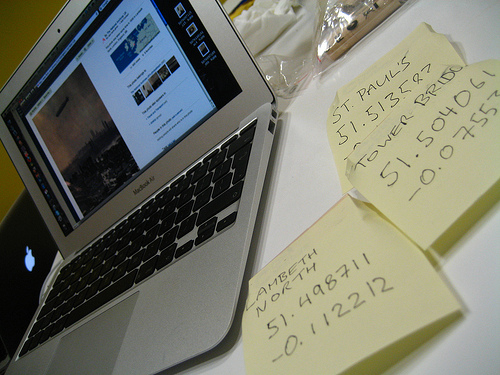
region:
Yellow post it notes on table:
[262, 12, 495, 373]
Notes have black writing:
[261, 19, 483, 354]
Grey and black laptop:
[11, 3, 271, 370]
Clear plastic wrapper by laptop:
[253, 7, 377, 110]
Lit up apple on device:
[8, 224, 45, 285]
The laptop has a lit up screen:
[8, 3, 258, 195]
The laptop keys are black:
[28, 121, 257, 338]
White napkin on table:
[237, 5, 319, 47]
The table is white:
[183, 8, 491, 351]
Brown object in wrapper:
[312, 6, 401, 61]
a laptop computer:
[2, 5, 394, 330]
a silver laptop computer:
[3, 12, 355, 374]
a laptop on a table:
[4, 8, 371, 372]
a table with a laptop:
[4, 6, 363, 362]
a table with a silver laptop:
[7, 16, 405, 373]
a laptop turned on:
[4, 6, 336, 368]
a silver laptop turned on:
[4, 5, 371, 355]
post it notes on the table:
[205, 23, 490, 366]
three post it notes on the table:
[221, 28, 496, 305]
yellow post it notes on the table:
[219, 53, 498, 358]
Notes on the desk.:
[303, 42, 496, 235]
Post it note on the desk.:
[245, 247, 462, 372]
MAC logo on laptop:
[7, 215, 64, 284]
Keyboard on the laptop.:
[30, 229, 302, 345]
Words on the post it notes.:
[318, 84, 483, 186]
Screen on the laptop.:
[8, 30, 288, 187]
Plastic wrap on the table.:
[258, 13, 397, 74]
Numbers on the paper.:
[256, 249, 443, 361]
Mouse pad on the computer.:
[52, 313, 161, 372]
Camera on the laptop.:
[28, 12, 77, 44]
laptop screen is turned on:
[0, 1, 249, 183]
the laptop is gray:
[3, 1, 243, 355]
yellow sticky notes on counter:
[229, 48, 479, 356]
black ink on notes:
[240, 62, 497, 350]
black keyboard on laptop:
[28, 201, 303, 311]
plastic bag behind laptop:
[228, 1, 410, 123]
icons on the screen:
[163, 0, 237, 83]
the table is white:
[243, 26, 495, 371]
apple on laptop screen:
[16, 233, 44, 280]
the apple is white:
[13, 241, 62, 290]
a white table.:
[278, 160, 325, 206]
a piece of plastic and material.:
[230, 0, 397, 55]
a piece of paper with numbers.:
[371, 60, 496, 201]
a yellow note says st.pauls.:
[326, 50, 431, 120]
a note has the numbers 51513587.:
[330, 45, 435, 156]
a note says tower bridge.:
[345, 45, 475, 210]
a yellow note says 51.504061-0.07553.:
[376, 62, 499, 224]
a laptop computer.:
[2, 0, 283, 372]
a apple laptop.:
[1, 181, 58, 355]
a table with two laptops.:
[0, 0, 496, 372]